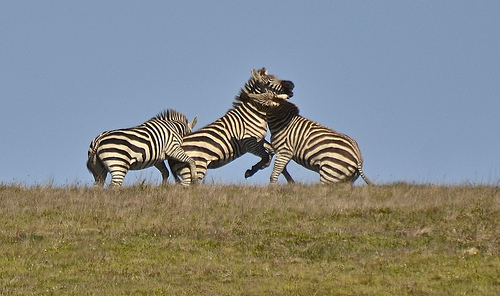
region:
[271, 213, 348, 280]
the zebras is fighting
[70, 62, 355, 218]
the zebras is fighting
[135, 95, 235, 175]
the zebras is fighting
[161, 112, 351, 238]
the zebras is fighting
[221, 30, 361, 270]
the zebras is fighting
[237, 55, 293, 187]
the zebras is fighting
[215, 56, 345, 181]
the zebras is fighting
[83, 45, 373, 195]
three zebras fighting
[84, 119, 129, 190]
rear end of black and white zebra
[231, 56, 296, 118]
two black and white zebra heads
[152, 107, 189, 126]
black and white zebra mane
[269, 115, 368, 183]
black and white zebra body at an angle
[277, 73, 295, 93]
dark zebra snout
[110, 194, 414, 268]
light green and brown scrub grass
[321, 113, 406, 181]
back end of zebra with blue sky in background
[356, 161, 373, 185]
striped zebra tail pointing down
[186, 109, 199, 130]
light colored zebra ear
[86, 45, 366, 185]
a trio of zebras fighting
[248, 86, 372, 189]
a zebra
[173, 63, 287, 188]
a zebra jumping up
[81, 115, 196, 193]
a zebra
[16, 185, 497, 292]
a small grassy hill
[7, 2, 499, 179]
a clear blue sky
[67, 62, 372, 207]
three zebras on a small hill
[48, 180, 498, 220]
tall grass on the hill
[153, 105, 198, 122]
the mane of a zebra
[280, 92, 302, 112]
the mane of a zebra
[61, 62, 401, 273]
three zebras are playing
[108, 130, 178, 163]
this is a zebra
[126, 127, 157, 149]
the zebra has white and black strips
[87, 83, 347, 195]
they are three zebras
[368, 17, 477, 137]
this is the sky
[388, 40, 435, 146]
the sky is blue in color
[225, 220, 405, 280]
this is a grass area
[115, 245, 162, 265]
the grass is green in color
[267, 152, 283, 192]
this is the leg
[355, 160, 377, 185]
this is the tail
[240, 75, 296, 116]
the zebras are fighting